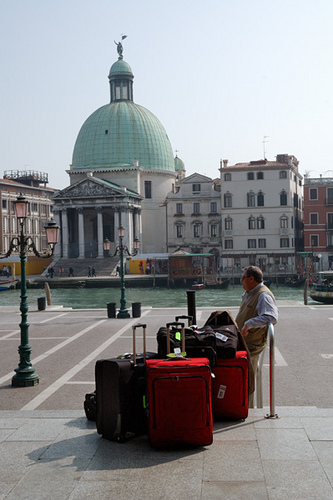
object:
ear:
[250, 276, 254, 284]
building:
[50, 173, 144, 260]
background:
[0, 151, 330, 269]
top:
[235, 284, 278, 354]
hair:
[245, 265, 263, 283]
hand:
[241, 323, 249, 337]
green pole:
[11, 236, 40, 388]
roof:
[78, 42, 181, 170]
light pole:
[0, 192, 60, 387]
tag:
[217, 384, 226, 399]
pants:
[248, 346, 266, 409]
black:
[95, 354, 148, 443]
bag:
[144, 322, 215, 448]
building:
[0, 171, 55, 276]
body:
[234, 265, 278, 408]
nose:
[241, 278, 243, 282]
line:
[4, 313, 129, 417]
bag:
[211, 350, 249, 422]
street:
[7, 302, 332, 409]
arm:
[244, 294, 278, 331]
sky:
[9, 12, 331, 177]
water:
[3, 283, 316, 306]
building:
[65, 32, 178, 251]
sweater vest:
[235, 285, 276, 353]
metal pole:
[267, 323, 276, 417]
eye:
[243, 275, 245, 279]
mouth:
[242, 284, 244, 288]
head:
[240, 265, 263, 290]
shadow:
[25, 441, 208, 472]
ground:
[190, 453, 323, 496]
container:
[131, 302, 141, 317]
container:
[106, 302, 116, 318]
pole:
[117, 223, 130, 318]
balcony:
[1, 169, 48, 183]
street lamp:
[104, 224, 141, 319]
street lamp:
[0, 189, 60, 388]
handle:
[166, 321, 186, 356]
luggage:
[126, 322, 148, 443]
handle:
[132, 322, 147, 365]